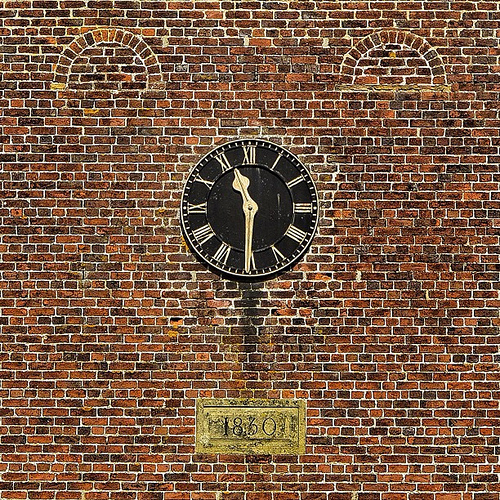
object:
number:
[265, 150, 285, 173]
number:
[283, 222, 307, 244]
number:
[265, 240, 288, 262]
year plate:
[194, 398, 306, 457]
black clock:
[179, 139, 319, 284]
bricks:
[336, 269, 494, 400]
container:
[194, 396, 305, 454]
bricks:
[3, 267, 170, 500]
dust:
[336, 151, 465, 359]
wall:
[0, 0, 500, 499]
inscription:
[223, 417, 277, 437]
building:
[0, 0, 497, 500]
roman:
[270, 223, 305, 266]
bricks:
[392, 174, 493, 279]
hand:
[231, 168, 258, 209]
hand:
[241, 207, 257, 273]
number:
[290, 198, 310, 219]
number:
[213, 151, 231, 174]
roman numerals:
[187, 201, 216, 247]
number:
[241, 144, 257, 166]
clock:
[179, 139, 320, 282]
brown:
[343, 268, 500, 435]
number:
[213, 242, 231, 265]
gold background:
[194, 398, 305, 454]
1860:
[224, 417, 278, 436]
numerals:
[213, 151, 233, 173]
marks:
[241, 139, 259, 166]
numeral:
[251, 250, 257, 269]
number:
[282, 174, 309, 190]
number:
[189, 223, 216, 246]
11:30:
[213, 141, 260, 275]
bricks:
[337, 3, 496, 500]